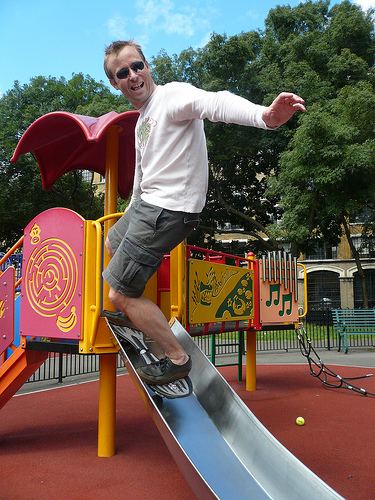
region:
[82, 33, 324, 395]
Man is skating on a slide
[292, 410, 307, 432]
Tennis ball on floor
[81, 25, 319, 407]
Man wears a long sleeve sweater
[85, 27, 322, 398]
Man uses sun glasses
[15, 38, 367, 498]
Person is in a playground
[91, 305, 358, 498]
Slide is gray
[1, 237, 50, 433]
Stairs to climb to slide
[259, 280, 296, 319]
Musical notes painted on board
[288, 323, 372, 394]
Rope ladders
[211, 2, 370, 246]
Big trees on side of playground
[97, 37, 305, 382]
Skateboarder going down slide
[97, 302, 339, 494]
Silver slide at playground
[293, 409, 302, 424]
Small ball on cement at playground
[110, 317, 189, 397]
Black and white skateboard under skater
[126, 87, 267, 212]
White shirt on skateboarder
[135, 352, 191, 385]
Black shoe on skateboarder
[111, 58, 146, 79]
Sunglasses on skateboarder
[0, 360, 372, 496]
Red cement floor of playground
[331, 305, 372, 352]
Green bench nearby playground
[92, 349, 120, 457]
Yellow pole supporting playground apparatus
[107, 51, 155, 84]
Sunglasses for eye protection.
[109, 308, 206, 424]
Wiggleboard for doing tricks.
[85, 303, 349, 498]
Slide with wiggle board on it.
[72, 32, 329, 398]
Man on wiggle board getting ready to do a dangerous trick.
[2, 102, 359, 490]
Playground jungle gym.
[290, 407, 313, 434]
Tennis ball sitting on the ground in the play area.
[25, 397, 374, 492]
Red rubber play area surface for protection against falls.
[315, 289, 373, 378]
Park bench for guardians to sit and watch their playing children.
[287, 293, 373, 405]
Rope ladder for entering the jungle gym.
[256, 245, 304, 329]
Musical instrument for children to play with on the jungle gym.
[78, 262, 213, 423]
skateboard on a metal slide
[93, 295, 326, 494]
a metal slide on a playground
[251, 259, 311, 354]
musical notes on the play structure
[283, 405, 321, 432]
a yellow tennis ball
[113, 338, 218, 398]
the man's black shoes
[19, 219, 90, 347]
a maze on the play structure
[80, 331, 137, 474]
large yellow metal poles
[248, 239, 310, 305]
metal pipes on the play structure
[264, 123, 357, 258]
green trees in the background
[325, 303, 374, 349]
a green park bench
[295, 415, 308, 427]
a green tennis ball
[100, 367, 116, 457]
a yellow support pole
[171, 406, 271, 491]
a smooth sliding surface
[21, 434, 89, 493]
red smooth clean surface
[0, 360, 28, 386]
beautiful orange sliding stairway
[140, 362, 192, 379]
black and brown shoe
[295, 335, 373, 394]
grey and white wire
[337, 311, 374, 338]
a blue metal bench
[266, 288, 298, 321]
green colored musical signs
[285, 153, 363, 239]
a beautiful green bush